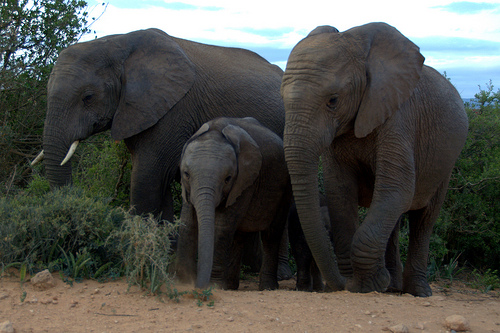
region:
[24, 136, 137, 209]
These are tusks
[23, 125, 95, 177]
The tusks are ivory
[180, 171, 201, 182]
This is an eye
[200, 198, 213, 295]
This is a trunk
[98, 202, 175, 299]
This is a picture of a weed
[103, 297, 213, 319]
This is a dirt path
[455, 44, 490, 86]
These are white clouds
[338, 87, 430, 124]
This is an ear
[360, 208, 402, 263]
This is a leg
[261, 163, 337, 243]
The trunk is long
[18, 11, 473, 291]
momma, daddy and baby elephant facing the camera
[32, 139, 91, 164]
white tusks on the poppa elephant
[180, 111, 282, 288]
gray baby elephant facing camera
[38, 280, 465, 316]
dirt in front of the elephants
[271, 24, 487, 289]
momma elephant facing camera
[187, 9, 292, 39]
blue sky off in distance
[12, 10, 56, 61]
trees with leaves to the left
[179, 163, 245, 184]
little baby elephants eyes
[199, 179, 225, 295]
the trunk on the little baby elephant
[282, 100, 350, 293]
momma elephants truck with ribs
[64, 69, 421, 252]
These are elephants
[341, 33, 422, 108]
This is an ear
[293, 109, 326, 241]
This is a trunk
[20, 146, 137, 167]
These are tusks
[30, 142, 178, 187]
The tusks are ivory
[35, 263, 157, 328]
This is a dirt path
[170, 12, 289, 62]
This is a picture of a cloudy sky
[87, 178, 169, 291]
This is an exotic weed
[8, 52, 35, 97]
this is an old tree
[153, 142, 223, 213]
This is an eye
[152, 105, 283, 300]
small black elephant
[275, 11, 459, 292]
large gray elephant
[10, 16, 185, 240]
large gray elephant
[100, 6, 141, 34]
white clouds in blue sky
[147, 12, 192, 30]
white clouds in blue sky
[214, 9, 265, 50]
white clouds in blue sky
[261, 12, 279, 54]
white clouds in blue sky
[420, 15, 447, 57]
white clouds in blue sky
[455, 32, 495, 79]
white clouds in blue sky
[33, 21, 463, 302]
There are three elephants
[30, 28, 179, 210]
One elephant has tusks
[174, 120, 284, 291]
One elephant is very small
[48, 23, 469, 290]
The elephants are grey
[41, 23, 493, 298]
The elephants have trunks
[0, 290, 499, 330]
The dirt is brown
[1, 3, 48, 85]
The leaves are green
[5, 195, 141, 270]
The grass is tall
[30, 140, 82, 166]
The tusks are white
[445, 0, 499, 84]
The sky has patches of blue